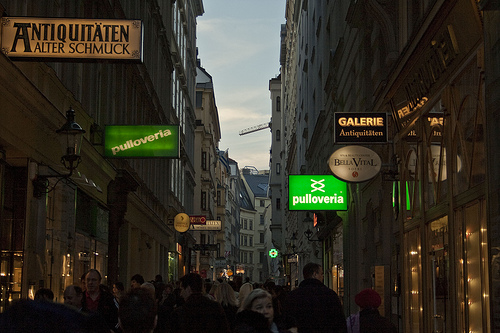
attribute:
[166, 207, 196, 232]
sign — tan colored, store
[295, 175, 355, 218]
store sign — lit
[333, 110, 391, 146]
sign — lit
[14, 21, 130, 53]
writing — black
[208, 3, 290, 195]
sunlight — fading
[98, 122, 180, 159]
sign — green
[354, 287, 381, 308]
hat — deep red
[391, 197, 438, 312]
window — lit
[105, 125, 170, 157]
sign — green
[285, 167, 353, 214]
logo — white, brand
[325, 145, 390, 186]
logo — red, brand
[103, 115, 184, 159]
sign — green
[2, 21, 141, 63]
sign — store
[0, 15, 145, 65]
sign — lit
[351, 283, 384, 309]
cap — red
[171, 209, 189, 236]
yellow sign — oval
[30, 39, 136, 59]
writing — black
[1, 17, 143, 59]
sign — lit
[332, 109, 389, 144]
sign — black, store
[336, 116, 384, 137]
lettering — white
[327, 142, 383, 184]
sign — white, oval